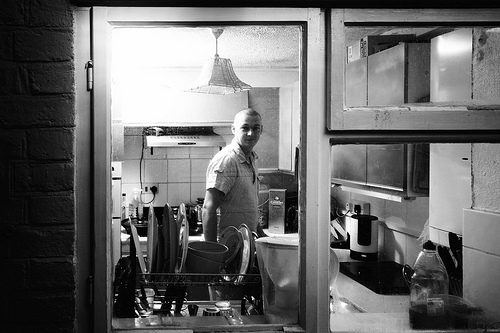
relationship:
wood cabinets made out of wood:
[348, 40, 428, 205] [335, 44, 414, 184]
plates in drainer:
[142, 205, 193, 273] [143, 267, 255, 309]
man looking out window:
[195, 100, 269, 275] [85, 7, 333, 328]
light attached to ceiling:
[172, 49, 284, 108] [107, 25, 387, 73]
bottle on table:
[410, 240, 452, 330] [329, 310, 496, 331]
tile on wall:
[382, 200, 422, 230] [349, 180, 445, 261]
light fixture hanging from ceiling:
[181, 27, 256, 97] [112, 27, 304, 71]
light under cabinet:
[138, 131, 224, 148] [118, 62, 253, 124]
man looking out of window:
[191, 108, 273, 244] [99, 7, 319, 326]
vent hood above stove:
[141, 124, 226, 151] [141, 203, 201, 236]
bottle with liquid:
[407, 237, 452, 331] [410, 300, 449, 330]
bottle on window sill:
[407, 237, 452, 331] [111, 313, 498, 331]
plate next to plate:
[141, 197, 196, 275] [174, 204, 189, 277]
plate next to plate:
[141, 197, 196, 275] [143, 204, 160, 276]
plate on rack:
[141, 197, 196, 275] [121, 256, 262, 311]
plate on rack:
[174, 204, 189, 277] [121, 256, 262, 311]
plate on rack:
[143, 204, 160, 276] [121, 256, 262, 311]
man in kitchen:
[188, 100, 280, 261] [104, 6, 497, 321]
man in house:
[196, 103, 271, 243] [1, 4, 494, 331]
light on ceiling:
[182, 21, 252, 97] [116, 31, 363, 67]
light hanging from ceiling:
[185, 56, 251, 97] [120, 29, 303, 37]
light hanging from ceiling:
[182, 21, 252, 97] [120, 29, 303, 37]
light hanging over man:
[185, 56, 251, 97] [198, 108, 263, 240]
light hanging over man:
[182, 21, 252, 97] [198, 108, 263, 240]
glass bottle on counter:
[406, 235, 456, 329] [108, 298, 498, 331]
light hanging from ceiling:
[183, 35, 256, 96] [108, 24, 299, 70]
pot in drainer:
[187, 240, 235, 284] [104, 196, 277, 316]